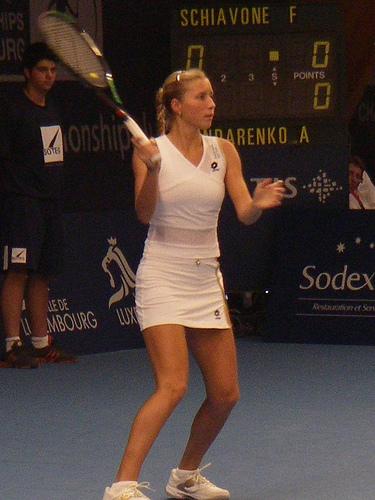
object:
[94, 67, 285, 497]
woman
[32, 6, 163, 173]
racket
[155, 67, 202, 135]
hair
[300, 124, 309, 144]
letter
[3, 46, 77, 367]
man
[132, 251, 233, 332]
skirt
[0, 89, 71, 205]
shirt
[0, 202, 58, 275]
shorts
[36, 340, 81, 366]
shoes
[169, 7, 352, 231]
scoreboard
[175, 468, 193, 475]
socks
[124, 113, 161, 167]
handle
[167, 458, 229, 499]
shoe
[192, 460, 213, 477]
lace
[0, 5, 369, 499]
tennis court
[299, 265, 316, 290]
letter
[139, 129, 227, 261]
shirt